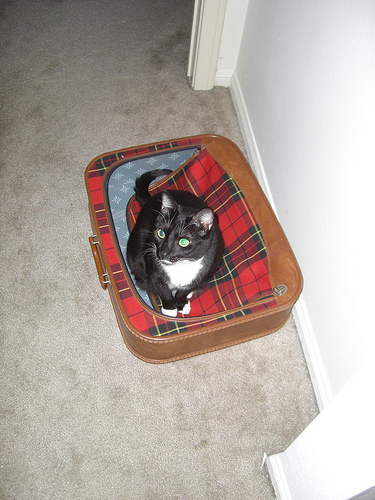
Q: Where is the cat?
A: In the suitcase.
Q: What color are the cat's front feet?
A: White.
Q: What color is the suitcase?
A: Red plaid.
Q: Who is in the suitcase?
A: The cat.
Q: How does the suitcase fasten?
A: A zipper.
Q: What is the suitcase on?
A: The floor.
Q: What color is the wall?
A: White.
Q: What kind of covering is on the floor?
A: Carpet.